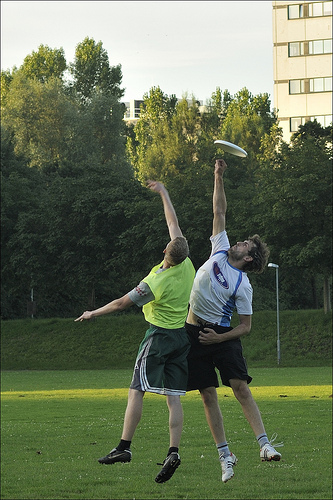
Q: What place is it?
A: It is a field.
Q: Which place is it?
A: It is a field.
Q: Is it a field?
A: Yes, it is a field.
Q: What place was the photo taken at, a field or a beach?
A: It was taken at a field.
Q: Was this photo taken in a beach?
A: No, the picture was taken in a field.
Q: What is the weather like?
A: It is clear.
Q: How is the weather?
A: It is clear.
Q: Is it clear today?
A: Yes, it is clear.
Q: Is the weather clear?
A: Yes, it is clear.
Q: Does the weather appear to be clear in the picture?
A: Yes, it is clear.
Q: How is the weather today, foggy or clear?
A: It is clear.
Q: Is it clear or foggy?
A: It is clear.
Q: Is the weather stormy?
A: No, it is clear.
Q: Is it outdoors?
A: Yes, it is outdoors.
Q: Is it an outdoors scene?
A: Yes, it is outdoors.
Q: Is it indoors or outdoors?
A: It is outdoors.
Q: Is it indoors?
A: No, it is outdoors.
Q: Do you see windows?
A: Yes, there are windows.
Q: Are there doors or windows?
A: Yes, there are windows.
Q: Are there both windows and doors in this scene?
A: No, there are windows but no doors.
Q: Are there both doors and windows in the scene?
A: No, there are windows but no doors.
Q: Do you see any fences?
A: No, there are no fences.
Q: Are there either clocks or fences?
A: No, there are no fences or clocks.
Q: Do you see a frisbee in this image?
A: Yes, there is a frisbee.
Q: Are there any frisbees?
A: Yes, there is a frisbee.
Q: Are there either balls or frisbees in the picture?
A: Yes, there is a frisbee.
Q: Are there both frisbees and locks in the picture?
A: No, there is a frisbee but no locks.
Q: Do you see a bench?
A: No, there are no benches.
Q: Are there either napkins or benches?
A: No, there are no benches or napkins.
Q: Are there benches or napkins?
A: No, there are no benches or napkins.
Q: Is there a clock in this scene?
A: No, there are no clocks.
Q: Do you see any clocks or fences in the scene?
A: No, there are no clocks or fences.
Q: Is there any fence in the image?
A: No, there are no fences.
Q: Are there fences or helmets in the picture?
A: No, there are no fences or helmets.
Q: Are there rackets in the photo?
A: No, there are no rackets.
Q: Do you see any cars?
A: No, there are no cars.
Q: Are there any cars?
A: No, there are no cars.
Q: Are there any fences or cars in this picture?
A: No, there are no cars or fences.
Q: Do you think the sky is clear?
A: Yes, the sky is clear.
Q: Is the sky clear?
A: Yes, the sky is clear.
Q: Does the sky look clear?
A: Yes, the sky is clear.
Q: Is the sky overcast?
A: No, the sky is clear.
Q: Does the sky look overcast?
A: No, the sky is clear.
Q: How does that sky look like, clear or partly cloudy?
A: The sky is clear.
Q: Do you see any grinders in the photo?
A: No, there are no grinders.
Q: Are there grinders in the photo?
A: No, there are no grinders.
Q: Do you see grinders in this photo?
A: No, there are no grinders.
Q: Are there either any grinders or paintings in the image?
A: No, there are no grinders or paintings.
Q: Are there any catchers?
A: No, there are no catchers.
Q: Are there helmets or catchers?
A: No, there are no catchers or helmets.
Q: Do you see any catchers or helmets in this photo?
A: No, there are no catchers or helmets.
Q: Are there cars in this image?
A: No, there are no cars.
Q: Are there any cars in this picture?
A: No, there are no cars.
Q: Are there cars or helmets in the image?
A: No, there are no cars or helmets.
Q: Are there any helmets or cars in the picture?
A: No, there are no cars or helmets.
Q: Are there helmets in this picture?
A: No, there are no helmets.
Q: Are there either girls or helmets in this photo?
A: No, there are no helmets or girls.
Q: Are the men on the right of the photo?
A: Yes, the men are on the right of the image.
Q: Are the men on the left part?
A: No, the men are on the right of the image.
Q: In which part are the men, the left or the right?
A: The men are on the right of the image.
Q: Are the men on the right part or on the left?
A: The men are on the right of the image.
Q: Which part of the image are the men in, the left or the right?
A: The men are on the right of the image.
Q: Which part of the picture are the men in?
A: The men are on the right of the image.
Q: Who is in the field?
A: The men are in the field.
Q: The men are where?
A: The men are in the field.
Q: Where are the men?
A: The men are in the field.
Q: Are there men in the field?
A: Yes, there are men in the field.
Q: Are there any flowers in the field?
A: No, there are men in the field.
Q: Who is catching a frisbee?
A: The men are catching a frisbee.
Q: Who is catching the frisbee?
A: The men are catching a frisbee.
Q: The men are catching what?
A: The men are catching a frisbee.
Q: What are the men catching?
A: The men are catching a frisbee.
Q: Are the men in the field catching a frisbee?
A: Yes, the men are catching a frisbee.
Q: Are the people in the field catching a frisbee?
A: Yes, the men are catching a frisbee.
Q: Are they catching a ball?
A: No, the men are catching a frisbee.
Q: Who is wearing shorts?
A: The men are wearing shorts.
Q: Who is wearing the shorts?
A: The men are wearing shorts.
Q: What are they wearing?
A: The men are wearing shorts.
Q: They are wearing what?
A: The men are wearing shorts.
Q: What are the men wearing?
A: The men are wearing shorts.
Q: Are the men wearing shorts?
A: Yes, the men are wearing shorts.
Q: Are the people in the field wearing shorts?
A: Yes, the men are wearing shorts.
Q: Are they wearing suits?
A: No, the men are wearing shorts.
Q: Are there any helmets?
A: No, there are no helmets.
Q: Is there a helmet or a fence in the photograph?
A: No, there are no helmets or fences.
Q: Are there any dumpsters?
A: No, there are no dumpsters.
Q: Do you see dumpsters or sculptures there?
A: No, there are no dumpsters or sculptures.